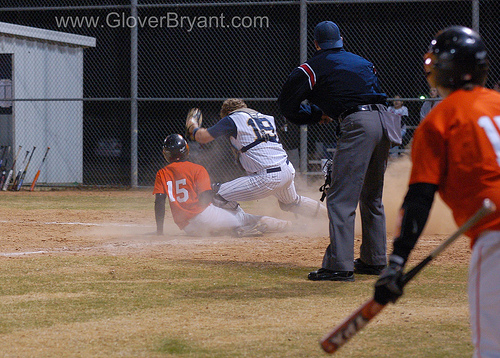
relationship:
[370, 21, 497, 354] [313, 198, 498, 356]
player holding bat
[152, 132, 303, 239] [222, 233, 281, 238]
player sliding into home plate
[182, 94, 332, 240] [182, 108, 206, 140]
catcher wearing glove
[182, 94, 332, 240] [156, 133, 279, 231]
catcher making play on runner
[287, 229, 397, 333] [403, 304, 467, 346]
batter in deck circle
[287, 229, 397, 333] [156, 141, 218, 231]
batter watching runner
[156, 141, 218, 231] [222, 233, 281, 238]
runner slides into home plate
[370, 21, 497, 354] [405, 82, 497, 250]
player in shirt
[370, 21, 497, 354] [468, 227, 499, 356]
player in white pants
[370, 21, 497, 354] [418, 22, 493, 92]
player in helmet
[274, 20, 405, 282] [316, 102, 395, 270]
umpire in pants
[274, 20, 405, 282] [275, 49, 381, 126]
umpire in shirt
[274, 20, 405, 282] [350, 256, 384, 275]
umpire in shoes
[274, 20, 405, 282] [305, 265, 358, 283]
umpire in shoes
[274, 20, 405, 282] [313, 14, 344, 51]
umpire in cap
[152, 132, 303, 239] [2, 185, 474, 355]
player on field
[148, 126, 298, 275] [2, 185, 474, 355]
man on field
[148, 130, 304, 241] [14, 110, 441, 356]
man on field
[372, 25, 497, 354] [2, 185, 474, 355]
man on field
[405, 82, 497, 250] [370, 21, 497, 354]
shirt on player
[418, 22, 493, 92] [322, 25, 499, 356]
helmet on batter